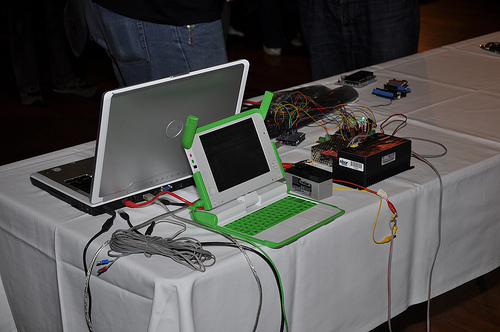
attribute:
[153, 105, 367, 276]
laptop — small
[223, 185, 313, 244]
keyboard — green 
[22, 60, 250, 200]
laptop — silver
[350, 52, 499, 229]
table — rectangular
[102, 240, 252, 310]
table cloth — white 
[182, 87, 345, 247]
laptop — silver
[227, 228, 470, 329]
wires — green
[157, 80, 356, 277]
laptop — green, white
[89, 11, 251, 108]
person — standing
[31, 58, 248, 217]
laptop — silver, white, white and silver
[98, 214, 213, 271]
cord — gray, bundled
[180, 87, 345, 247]
laptop computer — white, green, small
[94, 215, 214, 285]
cable — tied up, gray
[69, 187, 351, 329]
wires — gray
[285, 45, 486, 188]
table cloth — white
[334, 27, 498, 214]
table cloth — white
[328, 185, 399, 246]
wire — yellow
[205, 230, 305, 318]
wire — red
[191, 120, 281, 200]
screen — dark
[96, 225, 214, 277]
cable — gray, long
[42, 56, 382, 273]
laptop — white, green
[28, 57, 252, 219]
computer — red, silver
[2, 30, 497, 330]
folding table — long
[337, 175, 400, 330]
cords — red, yellow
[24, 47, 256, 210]
laptop — silver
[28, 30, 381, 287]
laptop — silver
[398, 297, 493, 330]
hardwood floor — dark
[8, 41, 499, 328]
table cloth — white, large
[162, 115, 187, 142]
logo — round, dell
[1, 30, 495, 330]
tablecloth — white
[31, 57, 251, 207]
trimmings — white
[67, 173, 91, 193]
keys — black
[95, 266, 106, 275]
end — red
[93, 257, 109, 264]
end — blue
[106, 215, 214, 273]
wires — gray